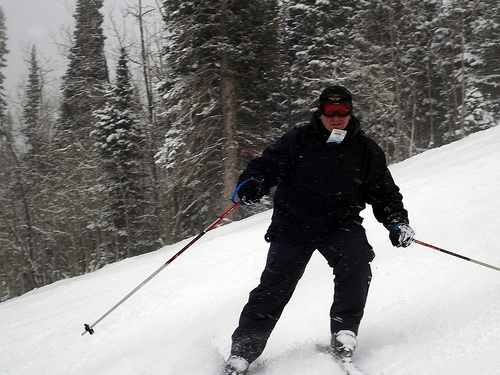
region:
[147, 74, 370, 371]
This is a person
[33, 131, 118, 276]
this is a tree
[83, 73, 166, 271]
this is a tree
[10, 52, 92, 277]
this is a tree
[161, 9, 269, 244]
this is a tree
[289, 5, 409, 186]
this is a tree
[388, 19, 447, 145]
this is a tree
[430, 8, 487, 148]
this is a tree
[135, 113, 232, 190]
these are branches on a tree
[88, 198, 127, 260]
these are branches on a tree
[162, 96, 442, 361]
the man is skiing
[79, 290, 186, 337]
pole in the snow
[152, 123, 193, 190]
snow on the trees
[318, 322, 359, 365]
shoe on the foot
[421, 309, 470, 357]
snow on the ground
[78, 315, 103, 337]
bottom of the pole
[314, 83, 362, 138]
face of the man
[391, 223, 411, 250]
glove on the hand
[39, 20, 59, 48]
the sky is hazy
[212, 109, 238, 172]
trunk of the tree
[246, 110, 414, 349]
A man skiing on snow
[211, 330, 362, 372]
Shoes covered with snow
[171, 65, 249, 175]
Trees at the back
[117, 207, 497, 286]
Skiing staffs in the photo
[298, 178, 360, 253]
A jacket in the photo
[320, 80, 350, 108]
A cap on the head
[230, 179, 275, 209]
Glove on the hand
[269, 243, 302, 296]
Black pant in the photo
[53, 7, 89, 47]
Cloudy skies in the background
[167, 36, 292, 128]
Trees covered with snow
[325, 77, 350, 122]
man has black hat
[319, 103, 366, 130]
man has black glasses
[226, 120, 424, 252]
man has black coat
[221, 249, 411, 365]
man has black pants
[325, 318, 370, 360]
white snow on boots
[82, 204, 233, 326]
red and silver ski poles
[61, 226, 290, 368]
white snow on hill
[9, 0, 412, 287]
thick stand of trees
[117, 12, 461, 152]
tall and green trees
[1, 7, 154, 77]
sky is grey and cold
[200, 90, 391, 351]
A person skating on snow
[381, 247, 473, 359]
A snow filled ground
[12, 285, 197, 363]
A snow filled ground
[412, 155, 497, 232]
A snow filled ground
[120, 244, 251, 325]
A snow filled ground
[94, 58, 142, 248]
A tall tree covered by snow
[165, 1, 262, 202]
A tall tree covered by snow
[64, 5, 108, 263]
A tall tree covered by snow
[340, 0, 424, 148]
A tall tree covered by snow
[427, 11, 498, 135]
A tall tree covered by snow